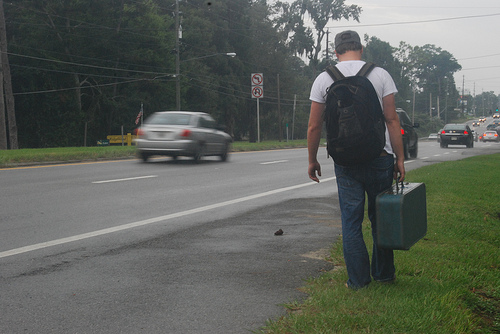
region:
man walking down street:
[265, 22, 465, 240]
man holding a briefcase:
[366, 151, 448, 268]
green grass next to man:
[424, 231, 470, 293]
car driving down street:
[131, 91, 242, 181]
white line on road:
[80, 156, 163, 216]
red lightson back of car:
[110, 119, 199, 146]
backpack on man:
[303, 55, 393, 166]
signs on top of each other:
[243, 61, 275, 112]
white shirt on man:
[315, 63, 397, 93]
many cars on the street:
[441, 116, 495, 161]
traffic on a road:
[46, 101, 498, 163]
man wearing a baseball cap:
[295, 23, 390, 58]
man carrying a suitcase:
[370, 149, 432, 256]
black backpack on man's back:
[306, 25, 395, 167]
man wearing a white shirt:
[300, 25, 411, 165]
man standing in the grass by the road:
[295, 23, 430, 311]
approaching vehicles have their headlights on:
[461, 98, 498, 137]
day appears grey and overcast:
[3, 3, 495, 328]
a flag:
[125, 87, 151, 139]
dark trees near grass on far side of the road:
[5, 3, 449, 170]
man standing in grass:
[296, 25, 432, 296]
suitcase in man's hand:
[360, 170, 438, 257]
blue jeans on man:
[331, 147, 403, 289]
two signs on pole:
[244, 63, 271, 110]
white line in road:
[83, 169, 173, 201]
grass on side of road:
[422, 152, 480, 193]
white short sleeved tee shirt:
[305, 56, 402, 131]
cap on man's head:
[329, 24, 367, 54]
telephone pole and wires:
[138, 27, 193, 108]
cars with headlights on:
[468, 112, 494, 133]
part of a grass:
[401, 259, 432, 299]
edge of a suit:
[379, 193, 417, 250]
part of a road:
[203, 277, 241, 322]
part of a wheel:
[185, 122, 207, 167]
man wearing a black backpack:
[307, 25, 427, 291]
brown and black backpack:
[325, 61, 390, 167]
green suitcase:
[372, 177, 433, 251]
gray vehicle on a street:
[131, 109, 238, 171]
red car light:
[181, 127, 192, 138]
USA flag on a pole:
[131, 100, 144, 125]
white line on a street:
[87, 170, 169, 185]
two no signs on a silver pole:
[250, 73, 265, 142]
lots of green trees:
[0, 12, 320, 142]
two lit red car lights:
[441, 127, 470, 137]